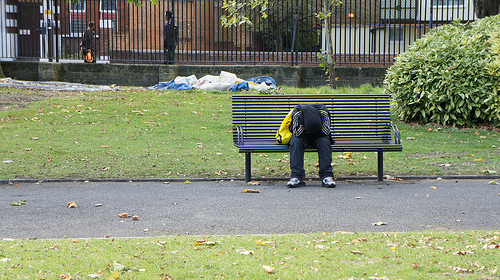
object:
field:
[0, 96, 216, 179]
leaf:
[103, 167, 109, 171]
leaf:
[81, 158, 85, 160]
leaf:
[24, 148, 32, 151]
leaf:
[167, 170, 172, 175]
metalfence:
[1, 0, 476, 65]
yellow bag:
[275, 109, 294, 145]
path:
[1, 177, 500, 238]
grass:
[1, 85, 498, 177]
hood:
[302, 110, 322, 134]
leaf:
[437, 162, 451, 167]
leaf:
[483, 169, 497, 174]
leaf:
[372, 221, 387, 226]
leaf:
[240, 247, 254, 256]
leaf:
[101, 145, 109, 147]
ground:
[3, 77, 499, 278]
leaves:
[66, 201, 78, 209]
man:
[277, 103, 338, 188]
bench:
[232, 95, 404, 183]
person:
[80, 21, 101, 64]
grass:
[0, 234, 499, 280]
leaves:
[261, 265, 273, 273]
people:
[160, 10, 178, 65]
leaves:
[356, 237, 368, 245]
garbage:
[150, 70, 279, 95]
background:
[0, 0, 499, 89]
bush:
[382, 13, 499, 129]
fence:
[0, 0, 477, 66]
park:
[0, 88, 499, 280]